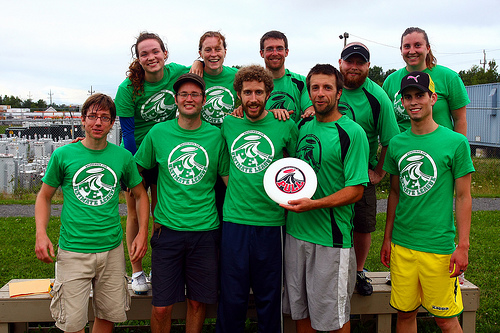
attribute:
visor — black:
[339, 44, 373, 64]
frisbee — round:
[259, 154, 321, 210]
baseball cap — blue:
[340, 43, 369, 61]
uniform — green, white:
[138, 113, 224, 232]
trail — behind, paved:
[0, 197, 500, 221]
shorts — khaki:
[48, 245, 135, 331]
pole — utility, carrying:
[336, 25, 370, 46]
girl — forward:
[113, 33, 203, 298]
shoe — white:
[128, 269, 148, 294]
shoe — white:
[146, 270, 153, 287]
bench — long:
[2, 264, 499, 331]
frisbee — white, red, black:
[263, 157, 318, 205]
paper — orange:
[8, 279, 51, 296]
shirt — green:
[285, 113, 373, 249]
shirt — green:
[379, 121, 474, 261]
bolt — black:
[452, 273, 462, 304]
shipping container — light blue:
[462, 80, 498, 153]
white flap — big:
[130, 269, 142, 279]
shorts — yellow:
[382, 237, 471, 320]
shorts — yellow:
[384, 244, 468, 319]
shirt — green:
[36, 138, 145, 255]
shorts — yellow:
[388, 237, 463, 318]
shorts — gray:
[285, 235, 357, 327]